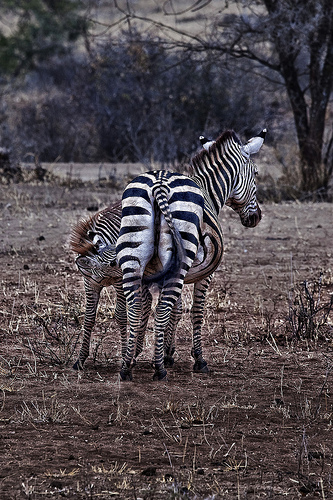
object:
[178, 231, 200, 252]
stripes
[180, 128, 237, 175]
comb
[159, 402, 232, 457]
twigs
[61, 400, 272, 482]
dirt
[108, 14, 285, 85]
branches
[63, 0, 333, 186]
tree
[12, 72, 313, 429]
field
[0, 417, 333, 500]
bush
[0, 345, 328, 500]
ground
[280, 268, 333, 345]
bush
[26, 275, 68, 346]
brush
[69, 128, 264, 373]
mother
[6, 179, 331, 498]
grassland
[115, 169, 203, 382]
zebra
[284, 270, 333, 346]
thistle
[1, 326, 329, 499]
grass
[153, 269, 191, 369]
leg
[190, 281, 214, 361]
leg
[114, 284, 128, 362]
leg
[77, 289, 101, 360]
leg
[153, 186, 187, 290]
tail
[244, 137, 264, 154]
ear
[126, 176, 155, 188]
stripes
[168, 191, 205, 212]
stripes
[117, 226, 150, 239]
stripes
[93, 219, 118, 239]
stripes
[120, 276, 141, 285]
stripes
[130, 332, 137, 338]
stripes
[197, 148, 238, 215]
stripes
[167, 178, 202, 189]
stripes